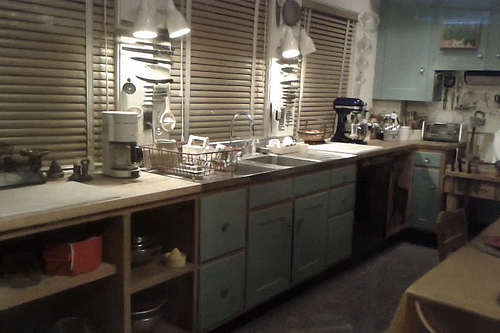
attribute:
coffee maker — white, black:
[98, 106, 155, 182]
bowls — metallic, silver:
[129, 229, 172, 332]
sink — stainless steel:
[228, 138, 318, 187]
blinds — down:
[2, 1, 360, 134]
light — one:
[133, 7, 319, 75]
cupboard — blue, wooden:
[377, 1, 498, 116]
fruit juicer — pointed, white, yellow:
[157, 242, 193, 270]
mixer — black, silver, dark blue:
[328, 91, 369, 150]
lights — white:
[131, 2, 329, 68]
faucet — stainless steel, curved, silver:
[225, 110, 256, 155]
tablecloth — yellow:
[384, 224, 499, 332]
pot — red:
[45, 236, 111, 278]